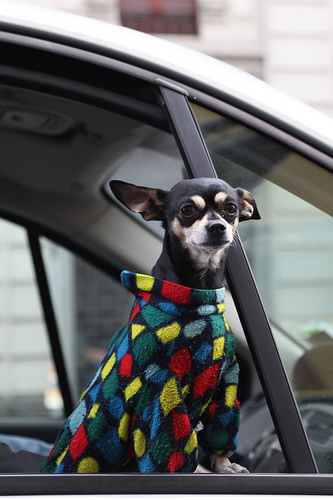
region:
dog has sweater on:
[47, 308, 237, 476]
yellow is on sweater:
[153, 314, 182, 351]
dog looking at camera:
[104, 150, 294, 274]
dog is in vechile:
[1, 97, 330, 379]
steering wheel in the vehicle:
[252, 406, 331, 482]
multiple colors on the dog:
[120, 309, 220, 475]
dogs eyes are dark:
[167, 195, 242, 219]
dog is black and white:
[164, 181, 240, 278]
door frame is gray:
[252, 96, 328, 491]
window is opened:
[1, 136, 275, 468]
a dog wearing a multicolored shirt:
[36, 171, 267, 474]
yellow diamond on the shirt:
[164, 379, 181, 411]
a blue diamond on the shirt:
[115, 334, 129, 360]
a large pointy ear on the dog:
[104, 173, 184, 228]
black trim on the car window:
[238, 275, 270, 339]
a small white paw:
[213, 457, 247, 475]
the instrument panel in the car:
[252, 425, 283, 469]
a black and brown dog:
[114, 157, 260, 279]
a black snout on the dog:
[205, 221, 224, 235]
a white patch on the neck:
[194, 246, 224, 265]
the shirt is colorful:
[97, 278, 249, 468]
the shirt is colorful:
[90, 292, 190, 411]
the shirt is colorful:
[69, 241, 218, 426]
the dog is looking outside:
[107, 147, 318, 437]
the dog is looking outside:
[69, 69, 256, 419]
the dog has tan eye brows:
[186, 194, 205, 211]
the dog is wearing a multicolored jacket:
[39, 267, 242, 470]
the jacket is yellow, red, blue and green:
[36, 260, 270, 473]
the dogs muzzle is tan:
[175, 201, 239, 274]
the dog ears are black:
[103, 177, 165, 237]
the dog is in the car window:
[1, 149, 332, 475]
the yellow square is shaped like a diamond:
[120, 373, 157, 412]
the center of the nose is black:
[204, 212, 221, 224]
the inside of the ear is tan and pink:
[236, 189, 257, 222]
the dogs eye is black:
[175, 201, 199, 224]